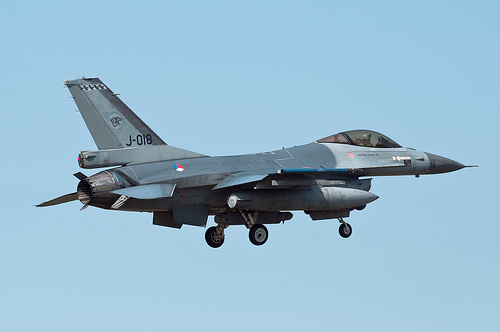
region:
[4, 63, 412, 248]
plane in the air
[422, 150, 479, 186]
nose of the plane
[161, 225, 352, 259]
wheels of the plane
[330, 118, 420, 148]
windshield of the plane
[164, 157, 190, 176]
logo on the plane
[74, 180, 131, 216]
back of the plane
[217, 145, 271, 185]
middle of the plane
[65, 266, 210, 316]
the sky is clear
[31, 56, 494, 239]
plane in the sky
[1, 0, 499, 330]
light blue sky with no visible clouds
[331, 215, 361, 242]
front wheel is down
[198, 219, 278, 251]
a pair of wheels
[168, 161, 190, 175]
red, white, and blue circle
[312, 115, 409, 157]
windows surrounded the cockpit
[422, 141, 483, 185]
nose of the plane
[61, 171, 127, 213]
engine on the back of the plane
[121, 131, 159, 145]
black writing on the tail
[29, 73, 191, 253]
tail of the plane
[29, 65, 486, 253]
A fighter jet in the air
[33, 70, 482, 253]
A fighter jet in the air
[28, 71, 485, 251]
A fighter jet in the air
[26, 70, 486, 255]
A fighter jet in the air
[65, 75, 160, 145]
tail of the jet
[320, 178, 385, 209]
a missle on the jet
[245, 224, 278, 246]
wheel on the airplane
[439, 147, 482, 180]
nose of the jet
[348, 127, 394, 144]
a windsheild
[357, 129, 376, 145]
pilot of the jet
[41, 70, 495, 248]
the jet is flying in the sky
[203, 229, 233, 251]
the wheel is black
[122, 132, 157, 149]
letters and numbers on the jet